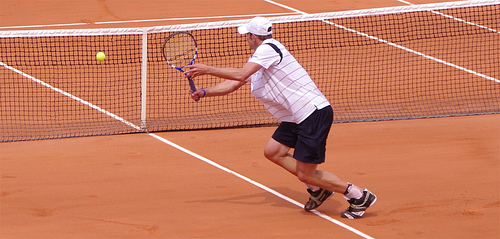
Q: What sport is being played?
A: Tennis.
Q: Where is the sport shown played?
A: Tennis court.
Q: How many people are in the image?
A: One.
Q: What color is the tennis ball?
A: Yellow.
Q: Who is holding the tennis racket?
A: The person.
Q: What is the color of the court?
A: Orange.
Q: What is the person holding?
A: Tennis racket.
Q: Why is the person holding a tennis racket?
A: Playing tennis.